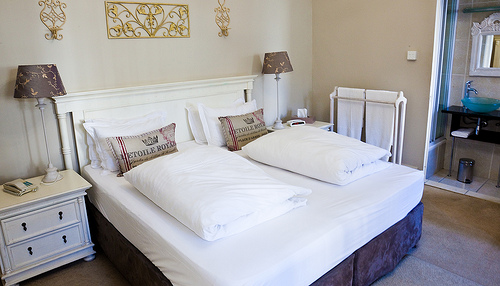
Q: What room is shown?
A: It is a bathroom.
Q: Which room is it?
A: It is a bathroom.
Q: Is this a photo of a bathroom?
A: Yes, it is showing a bathroom.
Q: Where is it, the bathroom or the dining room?
A: It is the bathroom.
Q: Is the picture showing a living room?
A: No, the picture is showing a bathroom.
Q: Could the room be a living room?
A: No, it is a bathroom.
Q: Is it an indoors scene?
A: Yes, it is indoors.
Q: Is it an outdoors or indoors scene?
A: It is indoors.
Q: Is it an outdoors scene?
A: No, it is indoors.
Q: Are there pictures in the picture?
A: No, there are no pictures.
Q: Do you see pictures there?
A: No, there are no pictures.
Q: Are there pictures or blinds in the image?
A: No, there are no pictures or blinds.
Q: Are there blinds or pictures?
A: No, there are no pictures or blinds.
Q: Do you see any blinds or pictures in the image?
A: No, there are no pictures or blinds.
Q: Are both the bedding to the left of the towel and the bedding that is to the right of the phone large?
A: Yes, both the bedding and the bedding are large.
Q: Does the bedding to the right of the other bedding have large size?
A: Yes, the bedding is large.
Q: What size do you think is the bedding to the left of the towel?
A: The bedding is large.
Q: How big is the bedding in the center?
A: The bedding is large.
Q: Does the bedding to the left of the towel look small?
A: No, the bedding is large.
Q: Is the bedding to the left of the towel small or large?
A: The bedding is large.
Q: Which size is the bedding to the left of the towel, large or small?
A: The bedding is large.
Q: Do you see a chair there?
A: No, there are no chairs.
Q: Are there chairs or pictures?
A: No, there are no chairs or pictures.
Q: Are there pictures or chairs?
A: No, there are no chairs or pictures.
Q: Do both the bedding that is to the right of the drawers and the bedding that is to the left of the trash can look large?
A: Yes, both the bedding and the bedding are large.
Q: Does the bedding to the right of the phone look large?
A: Yes, the bedding is large.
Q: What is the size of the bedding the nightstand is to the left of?
A: The bedding is large.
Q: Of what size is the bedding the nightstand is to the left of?
A: The bedding is large.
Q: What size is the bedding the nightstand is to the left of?
A: The bedding is large.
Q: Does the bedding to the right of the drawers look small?
A: No, the bedding is large.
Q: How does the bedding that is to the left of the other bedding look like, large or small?
A: The bedding is large.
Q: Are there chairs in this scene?
A: No, there are no chairs.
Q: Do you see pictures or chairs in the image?
A: No, there are no chairs or pictures.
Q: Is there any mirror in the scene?
A: Yes, there is a mirror.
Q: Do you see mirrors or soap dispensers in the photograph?
A: Yes, there is a mirror.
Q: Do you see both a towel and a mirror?
A: Yes, there are both a mirror and a towel.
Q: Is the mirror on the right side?
A: Yes, the mirror is on the right of the image.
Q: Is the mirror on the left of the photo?
A: No, the mirror is on the right of the image.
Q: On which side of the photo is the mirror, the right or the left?
A: The mirror is on the right of the image.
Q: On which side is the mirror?
A: The mirror is on the right of the image.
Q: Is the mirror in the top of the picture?
A: Yes, the mirror is in the top of the image.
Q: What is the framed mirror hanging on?
A: The mirror is hanging on the wall.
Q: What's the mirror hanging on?
A: The mirror is hanging on the wall.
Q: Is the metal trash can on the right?
A: Yes, the trash can is on the right of the image.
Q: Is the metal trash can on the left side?
A: No, the trashcan is on the right of the image.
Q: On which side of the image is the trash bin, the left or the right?
A: The trash bin is on the right of the image.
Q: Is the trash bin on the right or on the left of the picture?
A: The trash bin is on the right of the image.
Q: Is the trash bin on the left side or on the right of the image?
A: The trash bin is on the right of the image.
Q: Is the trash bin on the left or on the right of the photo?
A: The trash bin is on the right of the image.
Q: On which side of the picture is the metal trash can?
A: The trash can is on the right of the image.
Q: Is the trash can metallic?
A: Yes, the trash can is metallic.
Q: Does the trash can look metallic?
A: Yes, the trash can is metallic.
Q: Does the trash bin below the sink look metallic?
A: Yes, the trashcan is metallic.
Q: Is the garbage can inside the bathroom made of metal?
A: Yes, the garbage bin is made of metal.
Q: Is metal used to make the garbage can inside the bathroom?
A: Yes, the garbage bin is made of metal.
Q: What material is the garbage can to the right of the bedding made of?
A: The trashcan is made of metal.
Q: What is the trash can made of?
A: The trashcan is made of metal.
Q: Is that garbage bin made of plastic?
A: No, the garbage bin is made of metal.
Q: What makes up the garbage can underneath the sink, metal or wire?
A: The garbage can is made of metal.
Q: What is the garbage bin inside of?
A: The garbage bin is inside the bathroom.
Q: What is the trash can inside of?
A: The garbage bin is inside the bathroom.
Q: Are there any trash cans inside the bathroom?
A: Yes, there is a trash can inside the bathroom.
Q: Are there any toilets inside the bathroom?
A: No, there is a trash can inside the bathroom.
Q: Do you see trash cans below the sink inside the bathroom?
A: Yes, there is a trash can below the sink.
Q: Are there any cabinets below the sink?
A: No, there is a trash can below the sink.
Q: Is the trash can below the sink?
A: Yes, the trash can is below the sink.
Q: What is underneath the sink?
A: The trash bin is underneath the sink.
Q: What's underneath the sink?
A: The trash bin is underneath the sink.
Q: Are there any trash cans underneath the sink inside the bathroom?
A: Yes, there is a trash can underneath the sink.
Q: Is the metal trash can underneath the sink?
A: Yes, the trash bin is underneath the sink.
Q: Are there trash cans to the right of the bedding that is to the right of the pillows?
A: Yes, there is a trash can to the right of the bedding.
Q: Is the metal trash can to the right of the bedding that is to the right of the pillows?
A: Yes, the garbage bin is to the right of the bedding.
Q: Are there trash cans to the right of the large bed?
A: Yes, there is a trash can to the right of the bed.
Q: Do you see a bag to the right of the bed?
A: No, there is a trash can to the right of the bed.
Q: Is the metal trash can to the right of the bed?
A: Yes, the garbage bin is to the right of the bed.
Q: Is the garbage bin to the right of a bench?
A: No, the garbage bin is to the right of the bed.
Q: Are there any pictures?
A: No, there are no pictures.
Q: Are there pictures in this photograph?
A: No, there are no pictures.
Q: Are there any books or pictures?
A: No, there are no pictures or books.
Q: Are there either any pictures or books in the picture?
A: No, there are no pictures or books.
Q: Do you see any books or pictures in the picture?
A: No, there are no pictures or books.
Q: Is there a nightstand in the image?
A: Yes, there is a nightstand.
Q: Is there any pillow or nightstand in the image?
A: Yes, there is a nightstand.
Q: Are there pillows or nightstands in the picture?
A: Yes, there is a nightstand.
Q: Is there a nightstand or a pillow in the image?
A: Yes, there is a nightstand.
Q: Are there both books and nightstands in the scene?
A: No, there is a nightstand but no books.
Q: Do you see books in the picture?
A: No, there are no books.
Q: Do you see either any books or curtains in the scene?
A: No, there are no books or curtains.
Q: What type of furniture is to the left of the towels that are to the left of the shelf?
A: The piece of furniture is a nightstand.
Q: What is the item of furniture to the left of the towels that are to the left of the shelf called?
A: The piece of furniture is a nightstand.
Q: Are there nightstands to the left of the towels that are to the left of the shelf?
A: Yes, there is a nightstand to the left of the towels.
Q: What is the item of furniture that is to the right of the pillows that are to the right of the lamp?
A: The piece of furniture is a nightstand.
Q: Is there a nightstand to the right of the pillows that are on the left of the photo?
A: Yes, there is a nightstand to the right of the pillows.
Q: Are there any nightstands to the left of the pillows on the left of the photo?
A: No, the nightstand is to the right of the pillows.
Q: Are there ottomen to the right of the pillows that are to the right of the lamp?
A: No, there is a nightstand to the right of the pillows.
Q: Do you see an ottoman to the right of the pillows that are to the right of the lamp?
A: No, there is a nightstand to the right of the pillows.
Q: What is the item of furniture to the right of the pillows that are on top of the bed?
A: The piece of furniture is a nightstand.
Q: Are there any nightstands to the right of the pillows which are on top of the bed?
A: Yes, there is a nightstand to the right of the pillows.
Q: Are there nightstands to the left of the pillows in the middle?
A: No, the nightstand is to the right of the pillows.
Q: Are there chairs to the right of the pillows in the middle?
A: No, there is a nightstand to the right of the pillows.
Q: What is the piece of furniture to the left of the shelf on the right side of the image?
A: The piece of furniture is a nightstand.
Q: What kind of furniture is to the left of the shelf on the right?
A: The piece of furniture is a nightstand.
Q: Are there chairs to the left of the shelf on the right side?
A: No, there is a nightstand to the left of the shelf.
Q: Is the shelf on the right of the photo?
A: Yes, the shelf is on the right of the image.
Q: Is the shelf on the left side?
A: No, the shelf is on the right of the image.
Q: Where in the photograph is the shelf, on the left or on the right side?
A: The shelf is on the right of the image.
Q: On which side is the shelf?
A: The shelf is on the right of the image.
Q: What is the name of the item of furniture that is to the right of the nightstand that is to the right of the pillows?
A: The piece of furniture is a shelf.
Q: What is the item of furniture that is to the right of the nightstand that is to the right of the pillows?
A: The piece of furniture is a shelf.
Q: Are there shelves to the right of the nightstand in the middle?
A: Yes, there is a shelf to the right of the nightstand.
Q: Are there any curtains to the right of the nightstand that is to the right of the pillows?
A: No, there is a shelf to the right of the nightstand.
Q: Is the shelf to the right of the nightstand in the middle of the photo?
A: Yes, the shelf is to the right of the nightstand.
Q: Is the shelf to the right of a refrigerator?
A: No, the shelf is to the right of the nightstand.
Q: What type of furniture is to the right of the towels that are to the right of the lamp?
A: The piece of furniture is a shelf.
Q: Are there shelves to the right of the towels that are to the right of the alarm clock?
A: Yes, there is a shelf to the right of the towels.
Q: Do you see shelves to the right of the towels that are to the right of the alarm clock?
A: Yes, there is a shelf to the right of the towels.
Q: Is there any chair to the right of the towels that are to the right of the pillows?
A: No, there is a shelf to the right of the towels.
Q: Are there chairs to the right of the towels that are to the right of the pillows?
A: No, there is a shelf to the right of the towels.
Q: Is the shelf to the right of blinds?
A: No, the shelf is to the right of the towels.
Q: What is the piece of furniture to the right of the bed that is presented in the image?
A: The piece of furniture is a shelf.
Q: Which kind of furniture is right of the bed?
A: The piece of furniture is a shelf.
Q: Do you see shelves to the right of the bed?
A: Yes, there is a shelf to the right of the bed.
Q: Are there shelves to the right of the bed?
A: Yes, there is a shelf to the right of the bed.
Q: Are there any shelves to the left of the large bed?
A: No, the shelf is to the right of the bed.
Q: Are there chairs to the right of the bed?
A: No, there is a shelf to the right of the bed.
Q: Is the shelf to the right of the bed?
A: Yes, the shelf is to the right of the bed.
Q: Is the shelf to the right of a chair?
A: No, the shelf is to the right of the bed.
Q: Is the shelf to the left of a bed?
A: No, the shelf is to the right of a bed.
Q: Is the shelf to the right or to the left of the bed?
A: The shelf is to the right of the bed.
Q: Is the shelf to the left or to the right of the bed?
A: The shelf is to the right of the bed.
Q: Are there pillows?
A: Yes, there are pillows.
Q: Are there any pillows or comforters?
A: Yes, there are pillows.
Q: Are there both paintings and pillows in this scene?
A: No, there are pillows but no paintings.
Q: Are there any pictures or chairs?
A: No, there are no pictures or chairs.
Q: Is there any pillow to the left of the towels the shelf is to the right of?
A: Yes, there are pillows to the left of the towels.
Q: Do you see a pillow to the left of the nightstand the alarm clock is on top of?
A: Yes, there are pillows to the left of the nightstand.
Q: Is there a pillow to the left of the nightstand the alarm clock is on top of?
A: Yes, there are pillows to the left of the nightstand.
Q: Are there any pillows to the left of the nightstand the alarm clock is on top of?
A: Yes, there are pillows to the left of the nightstand.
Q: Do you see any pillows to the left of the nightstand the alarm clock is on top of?
A: Yes, there are pillows to the left of the nightstand.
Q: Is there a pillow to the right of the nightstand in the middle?
A: No, the pillows are to the left of the nightstand.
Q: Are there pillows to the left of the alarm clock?
A: Yes, there are pillows to the left of the alarm clock.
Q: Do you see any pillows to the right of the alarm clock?
A: No, the pillows are to the left of the alarm clock.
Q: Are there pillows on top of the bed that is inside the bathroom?
A: Yes, there are pillows on top of the bed.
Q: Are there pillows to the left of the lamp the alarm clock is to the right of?
A: Yes, there are pillows to the left of the lamp.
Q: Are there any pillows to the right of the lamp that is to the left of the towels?
A: No, the pillows are to the left of the lamp.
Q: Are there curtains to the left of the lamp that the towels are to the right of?
A: No, there are pillows to the left of the lamp.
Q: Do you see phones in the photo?
A: Yes, there is a phone.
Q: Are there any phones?
A: Yes, there is a phone.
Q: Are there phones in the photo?
A: Yes, there is a phone.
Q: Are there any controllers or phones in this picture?
A: Yes, there is a phone.